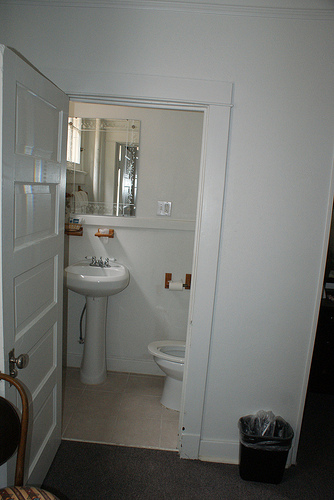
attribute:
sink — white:
[63, 256, 131, 293]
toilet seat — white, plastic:
[129, 303, 193, 397]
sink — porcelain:
[68, 262, 128, 294]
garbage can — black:
[237, 408, 295, 483]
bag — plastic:
[236, 409, 294, 451]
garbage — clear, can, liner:
[227, 410, 300, 491]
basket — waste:
[236, 408, 294, 478]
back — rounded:
[0, 369, 33, 483]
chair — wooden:
[1, 368, 56, 498]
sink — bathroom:
[57, 248, 132, 398]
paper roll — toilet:
[159, 270, 204, 301]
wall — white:
[192, 80, 316, 400]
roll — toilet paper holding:
[145, 263, 200, 288]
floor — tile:
[63, 362, 180, 458]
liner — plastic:
[234, 410, 294, 454]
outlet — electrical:
[155, 200, 176, 219]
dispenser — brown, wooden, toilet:
[161, 269, 194, 293]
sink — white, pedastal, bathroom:
[70, 254, 131, 391]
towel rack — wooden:
[65, 185, 89, 206]